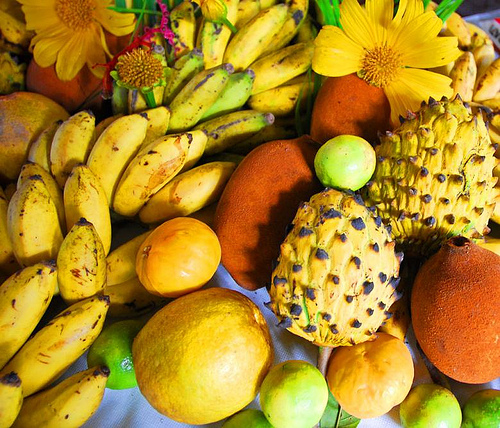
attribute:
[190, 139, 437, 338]
fruit — dark , brown 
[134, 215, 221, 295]
orange — yellow, fresh 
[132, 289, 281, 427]
orange — yellow, fresh 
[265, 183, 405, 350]
fruit — piled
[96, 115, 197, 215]
banana — yellow , fresh 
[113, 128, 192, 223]
banana — fresh , yellow 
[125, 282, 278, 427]
orange — large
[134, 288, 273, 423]
orange — fresh , yellow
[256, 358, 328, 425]
fruit — small, yellow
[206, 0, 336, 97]
banana — fresh , yellow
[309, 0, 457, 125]
flower — yellow , beautiful 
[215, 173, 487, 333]
durians — yellow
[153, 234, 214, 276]
orange — small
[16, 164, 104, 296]
banana — yellow , fresh 